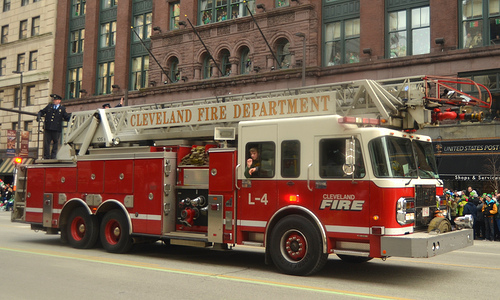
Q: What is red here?
A: Truck.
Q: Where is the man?
A: On the truck.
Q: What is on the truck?
A: A man.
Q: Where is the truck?
A: On the street.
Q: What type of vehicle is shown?
A: A firetruck.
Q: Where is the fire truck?
A: Driving down the street.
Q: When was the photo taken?
A: Daytime.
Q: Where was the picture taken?
A: In a parade.